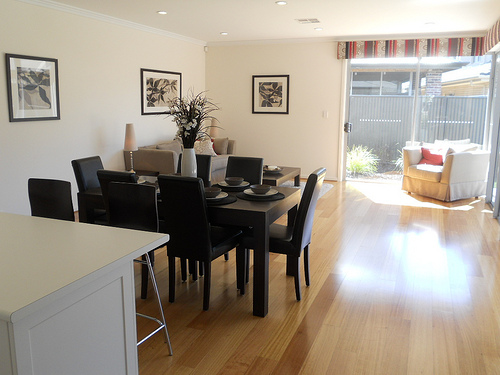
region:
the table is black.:
[25, 134, 328, 324]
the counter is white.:
[0, 203, 185, 371]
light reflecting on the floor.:
[331, 213, 471, 320]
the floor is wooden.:
[98, 163, 498, 364]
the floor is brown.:
[130, 165, 499, 372]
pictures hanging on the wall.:
[0, 45, 295, 130]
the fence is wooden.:
[344, 85, 489, 175]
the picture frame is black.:
[245, 67, 293, 119]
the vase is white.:
[173, 142, 200, 181]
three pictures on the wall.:
[4, 47, 296, 127]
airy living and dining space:
[4, 6, 499, 371]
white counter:
[2, 208, 177, 373]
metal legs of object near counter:
[91, 227, 182, 363]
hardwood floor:
[277, 290, 464, 370]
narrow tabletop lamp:
[111, 113, 142, 175]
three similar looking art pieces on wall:
[3, 41, 300, 126]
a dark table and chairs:
[25, 151, 332, 323]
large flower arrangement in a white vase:
[157, 79, 227, 192]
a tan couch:
[119, 108, 254, 184]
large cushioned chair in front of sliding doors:
[341, 60, 494, 212]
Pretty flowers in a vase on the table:
[168, 93, 215, 183]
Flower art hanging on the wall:
[241, 71, 304, 117]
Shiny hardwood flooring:
[341, 190, 450, 337]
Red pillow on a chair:
[406, 128, 453, 201]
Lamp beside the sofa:
[113, 114, 153, 178]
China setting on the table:
[197, 164, 289, 219]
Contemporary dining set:
[66, 131, 216, 229]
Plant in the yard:
[346, 131, 387, 196]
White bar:
[1, 208, 189, 361]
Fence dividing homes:
[350, 76, 497, 177]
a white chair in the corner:
[399, 140, 484, 197]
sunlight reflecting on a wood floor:
[354, 211, 481, 341]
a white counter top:
[4, 219, 156, 368]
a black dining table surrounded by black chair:
[54, 64, 352, 314]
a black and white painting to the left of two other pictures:
[10, 47, 74, 138]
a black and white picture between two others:
[133, 60, 183, 115]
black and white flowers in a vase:
[168, 94, 210, 153]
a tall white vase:
[178, 145, 200, 185]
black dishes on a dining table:
[219, 173, 284, 208]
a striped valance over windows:
[333, 40, 481, 57]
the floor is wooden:
[342, 220, 462, 358]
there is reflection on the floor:
[395, 210, 473, 308]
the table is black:
[86, 153, 318, 235]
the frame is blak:
[243, 70, 300, 117]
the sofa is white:
[398, 140, 483, 205]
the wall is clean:
[80, 85, 120, 120]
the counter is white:
[11, 230, 132, 280]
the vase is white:
[170, 143, 207, 169]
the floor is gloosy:
[307, 310, 473, 366]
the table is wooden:
[85, 164, 306, 251]